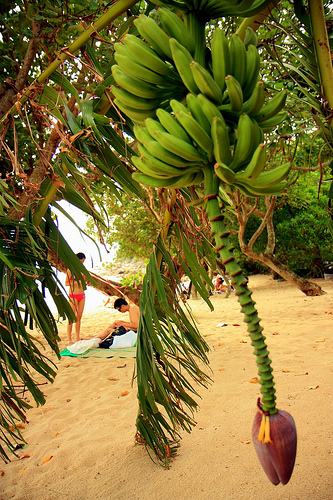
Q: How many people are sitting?
A: One.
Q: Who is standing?
A: The woman.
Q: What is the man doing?
A: Sitting.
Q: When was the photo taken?
A: Day time.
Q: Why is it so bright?
A: Sunny.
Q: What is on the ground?
A: Sand.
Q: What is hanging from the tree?
A: A plant.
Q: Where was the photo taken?
A: By the bananas.